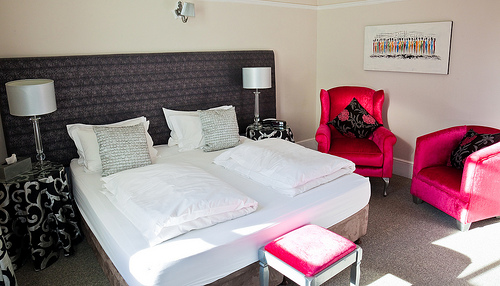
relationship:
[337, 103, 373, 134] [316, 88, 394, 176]
pillow in chair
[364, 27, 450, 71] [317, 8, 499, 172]
picture on wall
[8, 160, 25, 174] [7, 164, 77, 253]
tissues on table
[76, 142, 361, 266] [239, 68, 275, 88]
bed next to lamp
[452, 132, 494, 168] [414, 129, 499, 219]
pillow on chair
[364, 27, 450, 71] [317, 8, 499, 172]
picture hanging on wall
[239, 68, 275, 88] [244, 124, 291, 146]
lamp on table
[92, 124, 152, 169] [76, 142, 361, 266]
pillow on bed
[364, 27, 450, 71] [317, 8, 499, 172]
painting on wall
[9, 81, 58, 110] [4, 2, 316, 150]
lamp next to wall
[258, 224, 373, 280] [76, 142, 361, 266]
stool at foot of bed